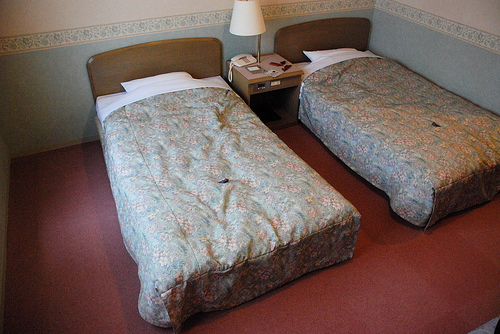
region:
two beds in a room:
[131, 6, 460, 311]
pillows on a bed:
[99, 47, 221, 122]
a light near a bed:
[224, 5, 306, 87]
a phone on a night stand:
[206, 0, 305, 109]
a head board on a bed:
[73, 15, 251, 135]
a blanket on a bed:
[106, 51, 383, 307]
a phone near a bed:
[220, 45, 270, 94]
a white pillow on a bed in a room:
[119, 28, 244, 130]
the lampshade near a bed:
[205, 3, 296, 78]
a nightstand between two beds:
[219, 13, 379, 153]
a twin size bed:
[68, 48, 334, 308]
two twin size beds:
[96, 47, 486, 289]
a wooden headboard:
[64, 33, 314, 208]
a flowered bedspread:
[107, 78, 366, 329]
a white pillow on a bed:
[102, 59, 249, 106]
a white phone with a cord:
[204, 40, 274, 85]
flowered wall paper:
[1, 5, 251, 40]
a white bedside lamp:
[215, 0, 285, 76]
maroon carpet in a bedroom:
[20, 162, 167, 324]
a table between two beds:
[218, 20, 354, 152]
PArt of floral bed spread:
[134, 260, 195, 315]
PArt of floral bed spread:
[190, 226, 244, 289]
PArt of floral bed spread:
[249, 223, 316, 291]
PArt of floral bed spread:
[273, 175, 327, 213]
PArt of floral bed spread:
[235, 123, 288, 173]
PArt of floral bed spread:
[195, 86, 255, 129]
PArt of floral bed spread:
[141, 95, 251, 174]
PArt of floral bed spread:
[321, 75, 393, 172]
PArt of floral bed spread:
[392, 138, 439, 193]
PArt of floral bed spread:
[443, 84, 487, 186]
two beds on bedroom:
[85, 16, 499, 330]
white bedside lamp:
[230, 0, 265, 62]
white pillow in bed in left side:
[121, 68, 199, 108]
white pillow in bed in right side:
[305, 43, 364, 68]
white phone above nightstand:
[229, 54, 258, 69]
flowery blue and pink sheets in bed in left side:
[94, 82, 359, 330]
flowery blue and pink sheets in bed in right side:
[300, 52, 495, 229]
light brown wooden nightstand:
[227, 54, 302, 128]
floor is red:
[8, 119, 497, 331]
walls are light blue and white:
[2, 3, 497, 163]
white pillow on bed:
[123, 74, 201, 99]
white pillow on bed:
[308, 40, 373, 68]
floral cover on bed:
[146, 114, 268, 214]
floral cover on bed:
[331, 88, 473, 178]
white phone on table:
[234, 50, 265, 77]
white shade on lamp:
[239, 5, 267, 31]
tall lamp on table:
[236, 8, 281, 49]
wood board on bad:
[96, 28, 229, 76]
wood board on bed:
[289, 25, 354, 45]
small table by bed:
[234, 48, 301, 130]